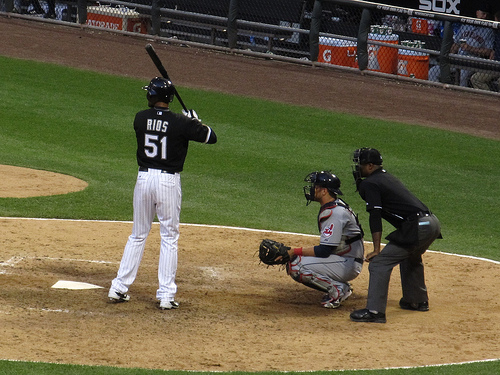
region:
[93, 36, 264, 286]
batter in the batter's box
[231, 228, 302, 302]
glove of the catcher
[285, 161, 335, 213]
helmet on the catcher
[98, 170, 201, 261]
striped pants of man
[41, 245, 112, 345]
home plate under batter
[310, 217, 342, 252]
logo on the jersey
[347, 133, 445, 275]
Umpire behind the catcher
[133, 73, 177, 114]
helmet on the batter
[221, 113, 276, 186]
green grass next to batter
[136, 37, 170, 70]
bat in the person's hand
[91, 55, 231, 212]
batter at the plate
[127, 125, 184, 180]
number 51 on the jersey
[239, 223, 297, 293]
glove on the catcher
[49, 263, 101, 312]
white plate under player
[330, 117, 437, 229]
umpire behind the catcher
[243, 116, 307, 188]
green grass next to player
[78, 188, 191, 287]
striped pants on player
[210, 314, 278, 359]
brown dirt under players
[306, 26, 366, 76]
cooler in the dugout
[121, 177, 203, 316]
the pants are white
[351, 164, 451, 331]
the umpire is bent over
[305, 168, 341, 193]
the helmet is black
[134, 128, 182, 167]
the number 51 is on the back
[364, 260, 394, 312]
the pants are grey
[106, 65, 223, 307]
he is baout to hit the ball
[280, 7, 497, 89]
the dug out area has players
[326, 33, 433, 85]
the containers are orange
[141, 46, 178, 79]
the baseball bat is wooden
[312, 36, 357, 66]
getorade is the sponsor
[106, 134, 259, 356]
A man in white pants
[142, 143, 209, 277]
A man in white pants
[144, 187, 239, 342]
A man in white pants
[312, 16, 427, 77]
orange and white Gatorade coolers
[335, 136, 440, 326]
umpire dressed in black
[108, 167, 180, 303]
white and black pinstripe pants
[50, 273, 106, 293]
home plate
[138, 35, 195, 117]
black wooden baseball bat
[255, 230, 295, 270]
the black leather catcher's mitt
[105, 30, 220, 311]
batter standing at home plate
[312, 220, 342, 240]
Cleveland Indian logo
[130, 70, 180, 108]
the batter's black helmet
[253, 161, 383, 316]
the player who is catching